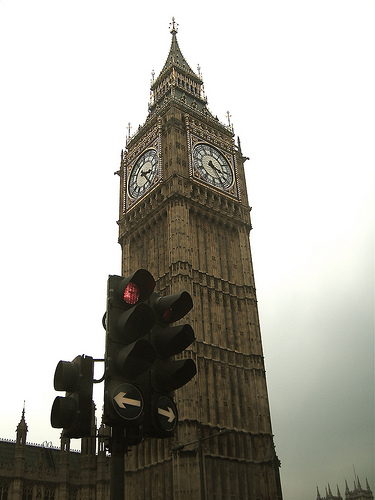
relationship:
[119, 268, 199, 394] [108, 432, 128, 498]
signal light on pole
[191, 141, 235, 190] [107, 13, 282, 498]
clock on clock tower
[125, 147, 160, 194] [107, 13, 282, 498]
clock on clock tower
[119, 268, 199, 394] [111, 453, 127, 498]
signal light on pole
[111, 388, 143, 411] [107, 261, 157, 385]
arrow attached to signal light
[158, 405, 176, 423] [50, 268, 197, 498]
arrow attached to signallight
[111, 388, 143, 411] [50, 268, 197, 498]
arrow attached to signallight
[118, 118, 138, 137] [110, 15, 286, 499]
cross attached to building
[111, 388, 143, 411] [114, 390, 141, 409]
arrow with a arrow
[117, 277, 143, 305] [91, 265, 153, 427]
red light on a traffic light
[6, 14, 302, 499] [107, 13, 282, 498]
building with a clock tower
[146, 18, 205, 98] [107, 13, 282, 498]
steeple on top of clock tower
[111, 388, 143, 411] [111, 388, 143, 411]
arrow on arrow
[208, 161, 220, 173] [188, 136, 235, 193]
hands on clock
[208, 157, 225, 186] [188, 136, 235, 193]
hands on clock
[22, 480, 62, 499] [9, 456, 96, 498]
windows on side of building